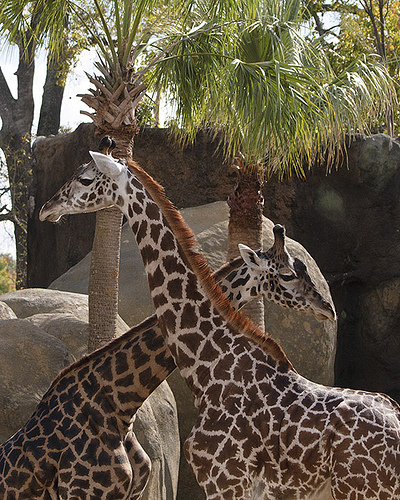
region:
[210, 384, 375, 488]
The giraffe has brown and white spots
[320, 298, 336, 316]
The nose of the giraffe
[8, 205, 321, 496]
Boulders behind the giraffes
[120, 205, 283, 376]
The giraffe has a long neck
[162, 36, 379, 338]
A tree behind the giraffes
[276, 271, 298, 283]
The right eye of the giraffe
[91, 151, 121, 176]
The left ear of the giraffe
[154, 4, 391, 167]
The leaves on the tree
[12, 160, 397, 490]
Two giraffes by the trees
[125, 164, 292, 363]
The giraffe has a mane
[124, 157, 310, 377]
the giraffi's mane is reddish brown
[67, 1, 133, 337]
the garaffi is under the palm tree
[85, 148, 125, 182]
the giraffis ear is white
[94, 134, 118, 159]
the horns have black knobs at the very top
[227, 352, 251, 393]
the white lines on this giraffi are like a barbed wire fence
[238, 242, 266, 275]
the inside of the ear is tan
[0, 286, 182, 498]
a large rock is behind the palm treet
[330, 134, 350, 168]
the bottom of the leaves are turning brown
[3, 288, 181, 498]
the rock is grayish in color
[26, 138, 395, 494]
two giraffis facing opposite direction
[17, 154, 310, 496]
these are two giraffes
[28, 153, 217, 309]
this is the neck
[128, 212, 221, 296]
the neck is thin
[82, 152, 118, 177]
this is the ear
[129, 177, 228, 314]
the neck is tall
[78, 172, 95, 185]
this is the eye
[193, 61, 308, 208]
this is a palm tree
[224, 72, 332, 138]
the tree is leafy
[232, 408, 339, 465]
the giraffe is brown and white in color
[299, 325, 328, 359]
this is a rock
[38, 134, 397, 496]
a giraffe with an orangey brown mane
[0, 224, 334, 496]
a giraffe bending forward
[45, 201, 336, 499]
a large boulder behind two giraffes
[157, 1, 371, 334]
a palm tree behind two giraffes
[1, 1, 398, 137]
a pale blue sky peeking through the trees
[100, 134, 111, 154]
a dark tipped horn on the head of a giraffe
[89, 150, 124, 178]
the white ear of a giraffe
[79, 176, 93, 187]
a giraffe eye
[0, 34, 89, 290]
a tree behind a boulder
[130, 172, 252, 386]
the long neck of a giraffe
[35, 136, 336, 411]
giraffe heads and necks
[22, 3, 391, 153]
palm leaves of tree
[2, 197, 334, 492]
round smooth gray rocks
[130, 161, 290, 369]
brown mane on neck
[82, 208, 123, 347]
bark of palm tree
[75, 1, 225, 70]
stems of palm leaves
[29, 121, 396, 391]
stone wall of enclosure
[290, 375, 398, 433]
light reflection on back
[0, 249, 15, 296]
tree tops on horizon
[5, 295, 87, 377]
shadows on rock tops